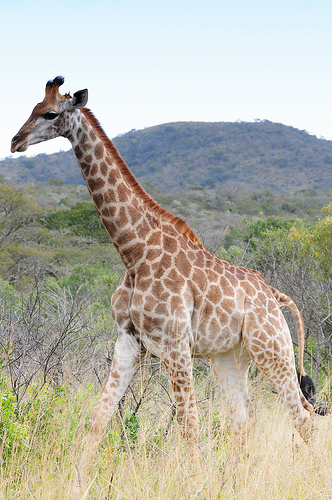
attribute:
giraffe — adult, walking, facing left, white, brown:
[10, 73, 331, 500]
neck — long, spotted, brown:
[68, 117, 186, 275]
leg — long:
[75, 327, 155, 499]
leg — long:
[164, 337, 209, 499]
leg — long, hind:
[214, 351, 261, 498]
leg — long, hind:
[243, 321, 331, 489]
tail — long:
[271, 284, 318, 413]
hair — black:
[295, 372, 318, 408]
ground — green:
[7, 207, 331, 497]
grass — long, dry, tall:
[13, 386, 330, 499]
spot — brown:
[163, 267, 190, 295]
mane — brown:
[82, 106, 203, 250]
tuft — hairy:
[293, 363, 321, 408]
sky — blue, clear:
[2, 1, 331, 173]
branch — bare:
[153, 382, 189, 463]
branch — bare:
[41, 279, 96, 387]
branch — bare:
[102, 367, 157, 498]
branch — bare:
[25, 267, 48, 347]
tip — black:
[302, 371, 314, 407]